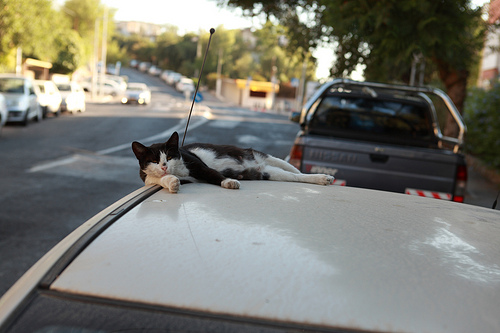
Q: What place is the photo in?
A: It is at the street.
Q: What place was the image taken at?
A: It was taken at the street.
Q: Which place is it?
A: It is a street.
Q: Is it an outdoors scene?
A: Yes, it is outdoors.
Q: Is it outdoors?
A: Yes, it is outdoors.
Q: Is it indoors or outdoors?
A: It is outdoors.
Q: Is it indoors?
A: No, it is outdoors.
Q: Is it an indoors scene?
A: No, it is outdoors.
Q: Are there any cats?
A: Yes, there is a cat.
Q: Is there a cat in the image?
A: Yes, there is a cat.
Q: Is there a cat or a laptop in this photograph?
A: Yes, there is a cat.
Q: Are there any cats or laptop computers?
A: Yes, there is a cat.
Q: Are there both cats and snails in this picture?
A: No, there is a cat but no snails.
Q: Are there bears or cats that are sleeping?
A: Yes, the cat is sleeping.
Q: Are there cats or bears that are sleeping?
A: Yes, the cat is sleeping.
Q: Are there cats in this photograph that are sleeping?
A: Yes, there is a cat that is sleeping.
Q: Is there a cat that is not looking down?
A: Yes, there is a cat that is sleeping.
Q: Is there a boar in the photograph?
A: No, there are no boars.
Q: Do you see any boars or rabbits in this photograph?
A: No, there are no boars or rabbits.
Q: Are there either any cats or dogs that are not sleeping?
A: No, there is a cat but it is sleeping.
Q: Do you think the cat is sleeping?
A: Yes, the cat is sleeping.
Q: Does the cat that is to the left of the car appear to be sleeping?
A: Yes, the cat is sleeping.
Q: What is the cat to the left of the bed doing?
A: The cat is sleeping.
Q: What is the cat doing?
A: The cat is sleeping.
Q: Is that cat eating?
A: No, the cat is sleeping.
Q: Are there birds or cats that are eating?
A: No, there is a cat but it is sleeping.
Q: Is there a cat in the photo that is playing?
A: No, there is a cat but it is sleeping.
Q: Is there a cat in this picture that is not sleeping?
A: No, there is a cat but it is sleeping.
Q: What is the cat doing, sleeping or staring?
A: The cat is sleeping.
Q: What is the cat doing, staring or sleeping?
A: The cat is sleeping.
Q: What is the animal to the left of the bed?
A: The animal is a cat.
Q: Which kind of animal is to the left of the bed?
A: The animal is a cat.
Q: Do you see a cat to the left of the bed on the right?
A: Yes, there is a cat to the left of the bed.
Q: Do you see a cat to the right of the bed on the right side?
A: No, the cat is to the left of the bed.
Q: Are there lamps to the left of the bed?
A: No, there is a cat to the left of the bed.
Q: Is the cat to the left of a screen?
A: No, the cat is to the left of the bed.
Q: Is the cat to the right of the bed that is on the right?
A: No, the cat is to the left of the bed.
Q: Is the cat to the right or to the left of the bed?
A: The cat is to the left of the bed.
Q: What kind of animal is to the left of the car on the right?
A: The animal is a cat.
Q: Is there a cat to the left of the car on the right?
A: Yes, there is a cat to the left of the car.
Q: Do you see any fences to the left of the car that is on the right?
A: No, there is a cat to the left of the car.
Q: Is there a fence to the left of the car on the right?
A: No, there is a cat to the left of the car.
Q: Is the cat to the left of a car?
A: Yes, the cat is to the left of a car.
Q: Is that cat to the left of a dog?
A: No, the cat is to the left of a car.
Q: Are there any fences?
A: No, there are no fences.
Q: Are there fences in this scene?
A: No, there are no fences.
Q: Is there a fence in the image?
A: No, there are no fences.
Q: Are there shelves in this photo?
A: No, there are no shelves.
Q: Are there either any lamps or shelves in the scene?
A: No, there are no shelves or lamps.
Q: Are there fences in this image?
A: No, there are no fences.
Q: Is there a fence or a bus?
A: No, there are no fences or buses.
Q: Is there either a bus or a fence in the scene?
A: No, there are no fences or buses.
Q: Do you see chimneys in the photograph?
A: No, there are no chimneys.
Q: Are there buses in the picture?
A: No, there are no buses.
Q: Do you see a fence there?
A: No, there are no fences.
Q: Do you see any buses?
A: No, there are no buses.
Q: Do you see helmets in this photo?
A: No, there are no helmets.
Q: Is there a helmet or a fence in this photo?
A: No, there are no helmets or fences.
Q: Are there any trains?
A: No, there are no trains.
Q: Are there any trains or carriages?
A: No, there are no trains or carriages.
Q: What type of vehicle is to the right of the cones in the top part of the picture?
A: The vehicle is a car.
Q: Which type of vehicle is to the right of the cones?
A: The vehicle is a car.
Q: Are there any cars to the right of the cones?
A: Yes, there is a car to the right of the cones.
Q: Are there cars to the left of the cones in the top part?
A: No, the car is to the right of the cones.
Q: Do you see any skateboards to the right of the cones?
A: No, there is a car to the right of the cones.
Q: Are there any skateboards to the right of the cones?
A: No, there is a car to the right of the cones.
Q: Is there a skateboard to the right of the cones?
A: No, there is a car to the right of the cones.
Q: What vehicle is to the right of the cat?
A: The vehicle is a car.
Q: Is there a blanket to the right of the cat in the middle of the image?
A: No, there is a car to the right of the cat.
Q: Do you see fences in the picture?
A: No, there are no fences.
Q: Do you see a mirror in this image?
A: No, there are no mirrors.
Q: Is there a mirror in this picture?
A: No, there are no mirrors.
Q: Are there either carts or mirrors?
A: No, there are no mirrors or carts.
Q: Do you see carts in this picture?
A: No, there are no carts.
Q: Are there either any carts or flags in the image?
A: No, there are no carts or flags.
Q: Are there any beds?
A: Yes, there is a bed.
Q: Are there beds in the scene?
A: Yes, there is a bed.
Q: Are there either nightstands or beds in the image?
A: Yes, there is a bed.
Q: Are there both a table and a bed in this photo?
A: No, there is a bed but no tables.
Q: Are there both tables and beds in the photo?
A: No, there is a bed but no tables.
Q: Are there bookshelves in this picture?
A: No, there are no bookshelves.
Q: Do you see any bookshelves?
A: No, there are no bookshelves.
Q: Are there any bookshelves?
A: No, there are no bookshelves.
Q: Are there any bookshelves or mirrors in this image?
A: No, there are no bookshelves or mirrors.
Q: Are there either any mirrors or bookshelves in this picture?
A: No, there are no bookshelves or mirrors.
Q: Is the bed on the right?
A: Yes, the bed is on the right of the image.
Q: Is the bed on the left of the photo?
A: No, the bed is on the right of the image.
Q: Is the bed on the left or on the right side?
A: The bed is on the right of the image.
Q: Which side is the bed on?
A: The bed is on the right of the image.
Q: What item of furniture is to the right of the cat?
A: The piece of furniture is a bed.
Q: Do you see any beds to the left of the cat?
A: No, the bed is to the right of the cat.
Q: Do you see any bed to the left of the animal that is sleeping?
A: No, the bed is to the right of the cat.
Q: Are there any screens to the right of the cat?
A: No, there is a bed to the right of the cat.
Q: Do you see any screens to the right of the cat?
A: No, there is a bed to the right of the cat.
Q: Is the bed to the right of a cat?
A: Yes, the bed is to the right of a cat.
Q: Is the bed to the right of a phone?
A: No, the bed is to the right of a cat.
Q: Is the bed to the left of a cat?
A: No, the bed is to the right of a cat.